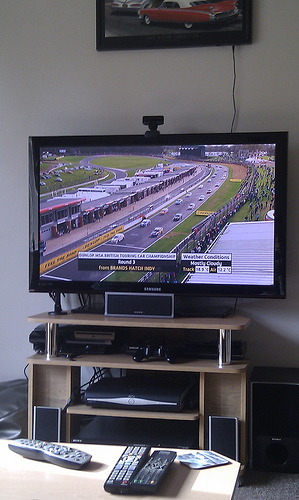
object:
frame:
[28, 133, 288, 296]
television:
[28, 115, 288, 299]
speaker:
[104, 292, 174, 318]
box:
[83, 376, 192, 413]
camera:
[141, 116, 164, 137]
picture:
[103, 0, 243, 39]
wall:
[0, 1, 298, 383]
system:
[28, 323, 130, 356]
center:
[26, 311, 248, 479]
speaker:
[250, 365, 299, 474]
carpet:
[234, 471, 298, 500]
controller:
[132, 344, 176, 363]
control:
[130, 449, 177, 493]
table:
[0, 438, 243, 500]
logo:
[144, 287, 161, 292]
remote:
[8, 437, 91, 471]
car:
[136, 1, 239, 30]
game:
[40, 144, 276, 285]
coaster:
[178, 449, 230, 470]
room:
[0, 1, 299, 500]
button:
[64, 452, 68, 455]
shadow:
[82, 460, 103, 474]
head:
[78, 452, 93, 470]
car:
[172, 213, 182, 221]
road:
[39, 163, 228, 281]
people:
[99, 171, 101, 176]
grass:
[91, 155, 150, 168]